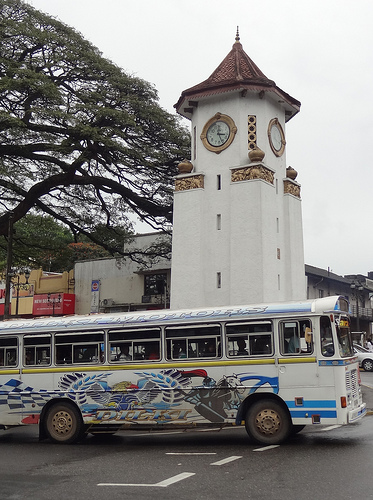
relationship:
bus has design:
[0, 295, 367, 445] [2, 368, 339, 417]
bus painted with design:
[0, 295, 367, 445] [2, 368, 339, 417]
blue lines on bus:
[286, 397, 338, 420] [6, 311, 364, 427]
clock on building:
[200, 112, 237, 154] [166, 22, 309, 309]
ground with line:
[0, 374, 372, 500] [252, 437, 280, 451]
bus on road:
[35, 309, 358, 436] [106, 436, 258, 466]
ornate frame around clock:
[213, 111, 236, 129] [208, 121, 229, 144]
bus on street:
[0, 295, 367, 445] [13, 412, 371, 492]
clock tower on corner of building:
[169, 25, 306, 308] [73, 228, 372, 350]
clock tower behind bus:
[169, 25, 306, 308] [14, 286, 358, 474]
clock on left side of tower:
[200, 112, 237, 154] [171, 23, 307, 309]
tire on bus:
[245, 403, 294, 446] [0, 295, 367, 445]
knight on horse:
[182, 375, 216, 409] [210, 372, 247, 409]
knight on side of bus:
[182, 375, 216, 409] [0, 295, 367, 445]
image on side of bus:
[56, 372, 189, 414] [0, 295, 367, 445]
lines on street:
[178, 444, 273, 481] [190, 444, 338, 494]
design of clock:
[248, 115, 257, 151] [191, 95, 237, 162]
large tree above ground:
[0, 0, 190, 320] [0, 374, 372, 500]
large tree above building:
[0, 0, 190, 320] [0, 25, 371, 338]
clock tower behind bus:
[170, 24, 306, 309] [0, 295, 367, 445]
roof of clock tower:
[85, 248, 133, 266] [170, 24, 306, 309]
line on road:
[101, 267, 163, 283] [233, 264, 309, 267]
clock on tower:
[200, 112, 237, 154] [171, 23, 307, 309]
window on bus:
[20, 331, 53, 367] [0, 295, 367, 445]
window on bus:
[50, 327, 107, 369] [0, 295, 367, 445]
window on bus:
[104, 320, 163, 363] [0, 295, 367, 445]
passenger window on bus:
[164, 322, 222, 362] [0, 295, 367, 445]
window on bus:
[276, 313, 316, 356] [0, 295, 367, 445]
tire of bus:
[41, 401, 81, 442] [0, 295, 367, 445]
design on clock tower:
[247, 114, 259, 150] [165, 22, 309, 431]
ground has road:
[0, 374, 372, 500] [57, 468, 69, 485]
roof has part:
[169, 27, 320, 133] [148, 18, 319, 131]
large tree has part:
[0, 0, 190, 320] [77, 56, 151, 163]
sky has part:
[295, 33, 346, 96] [321, 161, 355, 226]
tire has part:
[245, 399, 293, 446] [250, 391, 293, 445]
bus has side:
[0, 295, 367, 445] [6, 340, 301, 401]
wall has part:
[183, 222, 213, 291] [183, 228, 214, 297]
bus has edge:
[0, 295, 367, 445] [147, 389, 164, 410]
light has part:
[340, 395, 352, 409] [342, 394, 348, 402]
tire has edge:
[245, 399, 293, 446] [252, 413, 258, 427]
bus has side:
[0, 295, 367, 445] [273, 351, 293, 387]